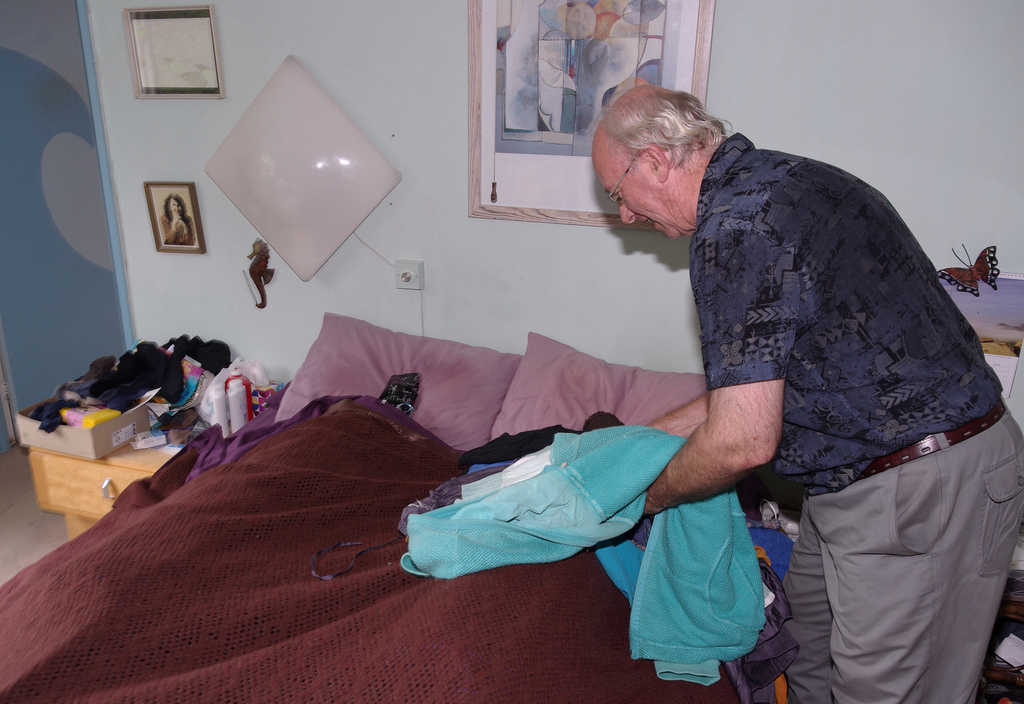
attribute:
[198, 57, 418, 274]
light — above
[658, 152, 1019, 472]
shirt — blue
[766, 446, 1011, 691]
pants — gray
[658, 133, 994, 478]
shirt — blue, black